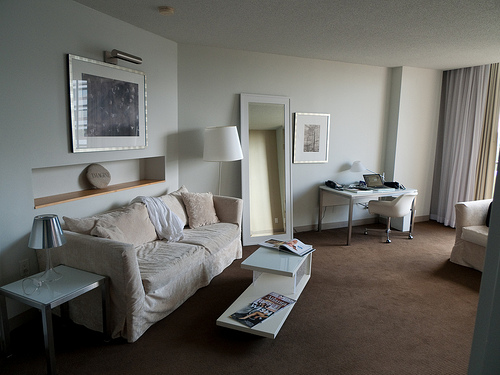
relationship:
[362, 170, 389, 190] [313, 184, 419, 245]
laptop on desk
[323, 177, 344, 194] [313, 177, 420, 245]
telephone on desk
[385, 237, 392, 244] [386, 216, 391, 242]
wheel on leg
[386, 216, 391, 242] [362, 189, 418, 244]
leg on chair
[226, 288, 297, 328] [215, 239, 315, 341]
magazine on coffee table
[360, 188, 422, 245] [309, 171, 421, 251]
chair near desk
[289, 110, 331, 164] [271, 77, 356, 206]
frame in wall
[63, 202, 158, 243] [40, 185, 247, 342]
cushion on couch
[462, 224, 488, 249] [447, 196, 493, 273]
cushion on couch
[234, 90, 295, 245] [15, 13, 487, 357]
mirror in room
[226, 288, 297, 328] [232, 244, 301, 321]
magazine on table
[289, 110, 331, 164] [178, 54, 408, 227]
frame on wall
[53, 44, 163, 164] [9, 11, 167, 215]
picture frame on wall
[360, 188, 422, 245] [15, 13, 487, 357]
chair in room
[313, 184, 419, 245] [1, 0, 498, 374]
desk in room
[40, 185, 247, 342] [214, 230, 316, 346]
couch in front of coffee table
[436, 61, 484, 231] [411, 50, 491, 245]
curatin hanging from window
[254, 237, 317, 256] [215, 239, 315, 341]
magazine on coffee table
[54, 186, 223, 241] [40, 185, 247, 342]
four cushions on couch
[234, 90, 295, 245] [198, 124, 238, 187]
mirror next to lamp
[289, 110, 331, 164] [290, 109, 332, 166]
frame on wall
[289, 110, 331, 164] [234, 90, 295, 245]
frame next to mirror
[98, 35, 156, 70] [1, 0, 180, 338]
lamp on wall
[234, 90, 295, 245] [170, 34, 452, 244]
mirror on wall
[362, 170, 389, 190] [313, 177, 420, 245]
laptop on desk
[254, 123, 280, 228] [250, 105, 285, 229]
reflection in mirror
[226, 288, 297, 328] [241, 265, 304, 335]
magazine on table